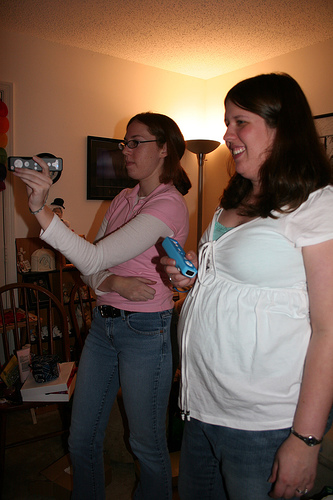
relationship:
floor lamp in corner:
[182, 139, 220, 257] [184, 74, 223, 266]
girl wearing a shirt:
[17, 114, 191, 499] [95, 182, 189, 312]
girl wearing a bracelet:
[17, 114, 191, 499] [28, 198, 46, 216]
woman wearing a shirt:
[160, 73, 332, 498] [176, 185, 332, 432]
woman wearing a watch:
[160, 73, 332, 498] [288, 428, 323, 447]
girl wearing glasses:
[17, 114, 191, 499] [117, 135, 168, 149]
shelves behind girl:
[1, 239, 96, 417] [17, 114, 191, 499]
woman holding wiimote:
[160, 73, 332, 498] [161, 237, 197, 279]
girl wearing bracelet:
[17, 114, 191, 499] [28, 198, 46, 216]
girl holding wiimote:
[17, 114, 191, 499] [6, 156, 63, 173]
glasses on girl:
[117, 135, 168, 149] [17, 114, 191, 499]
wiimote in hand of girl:
[6, 156, 63, 173] [17, 114, 191, 499]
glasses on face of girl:
[117, 135, 168, 149] [17, 114, 191, 499]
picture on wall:
[85, 135, 138, 201] [0, 31, 203, 365]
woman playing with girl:
[160, 73, 332, 498] [17, 114, 191, 499]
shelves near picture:
[1, 239, 96, 417] [85, 135, 138, 201]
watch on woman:
[288, 428, 323, 447] [160, 73, 332, 498]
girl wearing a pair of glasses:
[17, 114, 191, 499] [117, 135, 168, 149]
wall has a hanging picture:
[0, 31, 203, 365] [85, 135, 138, 201]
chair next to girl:
[1, 282, 70, 461] [17, 114, 191, 499]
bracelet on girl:
[28, 198, 46, 216] [17, 114, 191, 499]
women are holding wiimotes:
[12, 72, 332, 499] [8, 155, 198, 279]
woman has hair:
[160, 73, 332, 498] [217, 73, 332, 221]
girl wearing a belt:
[17, 114, 191, 499] [96, 304, 135, 319]